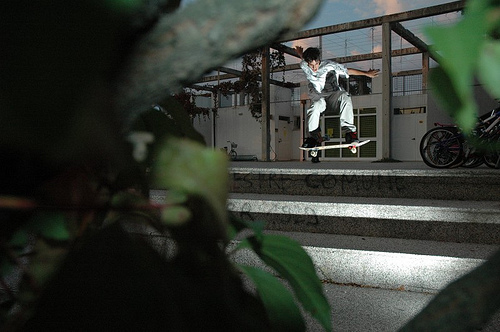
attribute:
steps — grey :
[223, 160, 499, 242]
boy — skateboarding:
[292, 41, 382, 145]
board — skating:
[291, 131, 374, 161]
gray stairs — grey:
[218, 165, 498, 267]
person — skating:
[294, 45, 380, 144]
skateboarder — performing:
[293, 39, 378, 163]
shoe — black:
[346, 133, 356, 146]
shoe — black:
[302, 136, 322, 148]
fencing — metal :
[249, 3, 399, 54]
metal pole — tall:
[379, 20, 394, 161]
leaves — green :
[132, 119, 378, 315]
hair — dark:
[292, 45, 335, 62]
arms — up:
[289, 46, 379, 80]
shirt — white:
[301, 62, 352, 99]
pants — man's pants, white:
[300, 98, 359, 138]